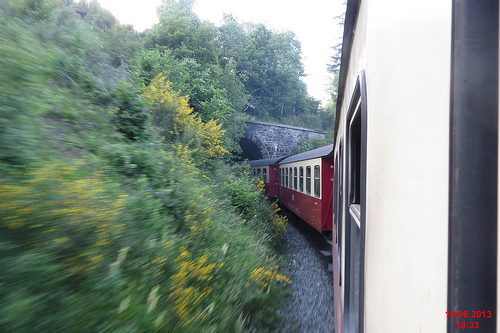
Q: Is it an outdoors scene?
A: Yes, it is outdoors.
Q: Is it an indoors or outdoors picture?
A: It is outdoors.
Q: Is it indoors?
A: No, it is outdoors.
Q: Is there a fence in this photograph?
A: No, there are no fences.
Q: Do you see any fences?
A: No, there are no fences.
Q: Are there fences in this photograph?
A: No, there are no fences.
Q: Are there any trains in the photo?
A: Yes, there is a train.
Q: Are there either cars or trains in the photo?
A: Yes, there is a train.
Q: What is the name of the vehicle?
A: The vehicle is a train.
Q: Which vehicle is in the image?
A: The vehicle is a train.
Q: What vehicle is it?
A: The vehicle is a train.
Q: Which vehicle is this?
A: That is a train.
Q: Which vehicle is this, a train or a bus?
A: That is a train.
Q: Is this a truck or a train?
A: This is a train.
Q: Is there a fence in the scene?
A: No, there are no fences.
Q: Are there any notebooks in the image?
A: No, there are no notebooks.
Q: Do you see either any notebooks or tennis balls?
A: No, there are no notebooks or tennis balls.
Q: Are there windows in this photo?
A: Yes, there is a window.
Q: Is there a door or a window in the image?
A: Yes, there is a window.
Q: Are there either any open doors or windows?
A: Yes, there is an open window.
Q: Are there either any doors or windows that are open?
A: Yes, the window is open.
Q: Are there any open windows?
A: Yes, there is an open window.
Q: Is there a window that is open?
A: Yes, there is a window that is open.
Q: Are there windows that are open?
A: Yes, there is a window that is open.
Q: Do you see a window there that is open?
A: Yes, there is a window that is open.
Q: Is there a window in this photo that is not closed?
A: Yes, there is a open window.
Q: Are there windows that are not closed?
A: Yes, there is a open window.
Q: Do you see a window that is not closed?
A: Yes, there is a open window.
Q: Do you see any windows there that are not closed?
A: Yes, there is a open window.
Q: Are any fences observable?
A: No, there are no fences.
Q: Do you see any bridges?
A: Yes, there is a bridge.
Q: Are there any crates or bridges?
A: Yes, there is a bridge.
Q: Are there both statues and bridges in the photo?
A: No, there is a bridge but no statues.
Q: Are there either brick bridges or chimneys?
A: Yes, there is a brick bridge.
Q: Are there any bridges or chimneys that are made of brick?
A: Yes, the bridge is made of brick.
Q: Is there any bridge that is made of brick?
A: Yes, there is a bridge that is made of brick.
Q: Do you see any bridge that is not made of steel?
A: Yes, there is a bridge that is made of brick.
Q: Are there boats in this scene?
A: No, there are no boats.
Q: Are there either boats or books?
A: No, there are no boats or books.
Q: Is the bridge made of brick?
A: Yes, the bridge is made of brick.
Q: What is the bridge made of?
A: The bridge is made of brick.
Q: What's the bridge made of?
A: The bridge is made of brick.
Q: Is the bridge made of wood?
A: No, the bridge is made of brick.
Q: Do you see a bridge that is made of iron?
A: No, there is a bridge but it is made of brick.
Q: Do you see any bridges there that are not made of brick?
A: No, there is a bridge but it is made of brick.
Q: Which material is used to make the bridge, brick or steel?
A: The bridge is made of brick.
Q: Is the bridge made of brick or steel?
A: The bridge is made of brick.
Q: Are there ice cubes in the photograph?
A: No, there are no ice cubes.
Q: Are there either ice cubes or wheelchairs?
A: No, there are no ice cubes or wheelchairs.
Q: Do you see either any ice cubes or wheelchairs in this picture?
A: No, there are no ice cubes or wheelchairs.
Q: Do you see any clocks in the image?
A: No, there are no clocks.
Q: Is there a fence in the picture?
A: No, there are no fences.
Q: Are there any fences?
A: No, there are no fences.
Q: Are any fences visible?
A: No, there are no fences.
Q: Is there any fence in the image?
A: No, there are no fences.